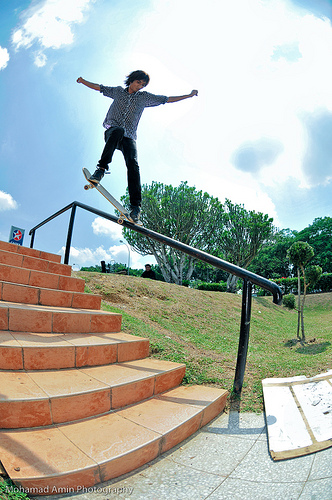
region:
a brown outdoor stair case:
[1, 239, 226, 495]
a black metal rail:
[20, 200, 285, 403]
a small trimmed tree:
[285, 238, 321, 344]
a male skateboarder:
[71, 66, 199, 228]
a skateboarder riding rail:
[22, 70, 284, 397]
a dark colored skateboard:
[81, 164, 139, 225]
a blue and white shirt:
[97, 82, 165, 137]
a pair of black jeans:
[97, 127, 142, 208]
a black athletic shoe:
[89, 165, 109, 184]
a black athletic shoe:
[125, 203, 142, 223]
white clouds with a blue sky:
[4, 2, 97, 70]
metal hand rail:
[27, 200, 289, 395]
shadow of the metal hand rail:
[3, 324, 280, 480]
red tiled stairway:
[1, 238, 230, 497]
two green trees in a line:
[118, 181, 274, 294]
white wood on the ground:
[260, 359, 330, 464]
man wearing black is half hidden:
[136, 261, 160, 280]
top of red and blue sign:
[5, 222, 27, 246]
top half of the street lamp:
[116, 238, 132, 275]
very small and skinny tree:
[281, 239, 324, 354]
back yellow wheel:
[81, 176, 100, 195]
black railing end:
[198, 245, 290, 312]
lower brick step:
[2, 428, 109, 489]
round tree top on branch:
[279, 238, 321, 267]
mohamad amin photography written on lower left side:
[3, 476, 141, 496]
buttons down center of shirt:
[115, 94, 132, 121]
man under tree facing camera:
[139, 259, 160, 284]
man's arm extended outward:
[161, 86, 208, 112]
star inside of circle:
[9, 223, 33, 242]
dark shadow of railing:
[228, 393, 274, 444]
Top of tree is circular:
[286, 240, 314, 266]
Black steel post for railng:
[231, 278, 252, 396]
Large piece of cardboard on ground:
[262, 375, 329, 460]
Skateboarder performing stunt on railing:
[75, 61, 201, 228]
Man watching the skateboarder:
[140, 262, 154, 276]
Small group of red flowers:
[280, 275, 288, 280]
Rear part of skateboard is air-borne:
[81, 167, 104, 190]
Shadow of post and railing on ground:
[204, 397, 265, 437]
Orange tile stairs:
[47, 359, 174, 423]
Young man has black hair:
[123, 69, 150, 92]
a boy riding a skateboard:
[55, 59, 207, 211]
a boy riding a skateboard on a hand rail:
[53, 72, 213, 262]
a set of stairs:
[13, 241, 88, 474]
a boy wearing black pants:
[78, 62, 193, 214]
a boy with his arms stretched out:
[56, 56, 208, 117]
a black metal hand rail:
[111, 241, 290, 386]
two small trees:
[290, 231, 314, 346]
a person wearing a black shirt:
[125, 257, 162, 286]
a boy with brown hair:
[108, 64, 164, 97]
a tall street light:
[115, 234, 133, 276]